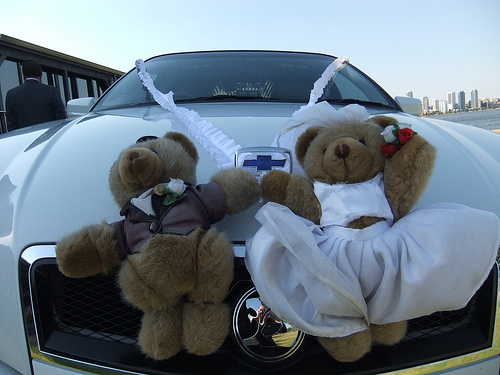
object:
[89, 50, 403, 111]
windshield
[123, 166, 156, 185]
mouth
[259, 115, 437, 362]
stuffed bear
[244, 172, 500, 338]
dress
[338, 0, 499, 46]
sky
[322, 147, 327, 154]
eye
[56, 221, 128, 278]
arm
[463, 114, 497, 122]
body water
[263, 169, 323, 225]
arm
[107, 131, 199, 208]
head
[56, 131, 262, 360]
bear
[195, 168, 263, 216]
arm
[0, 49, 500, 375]
car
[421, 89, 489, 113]
buildings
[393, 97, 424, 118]
mirror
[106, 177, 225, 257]
tuxedo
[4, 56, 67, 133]
man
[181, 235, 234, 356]
leg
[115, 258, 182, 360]
leg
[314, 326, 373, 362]
leg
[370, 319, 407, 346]
leg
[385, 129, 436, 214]
arm